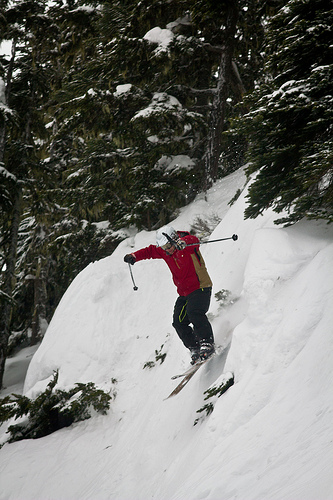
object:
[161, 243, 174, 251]
goggles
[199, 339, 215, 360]
shoes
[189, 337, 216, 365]
boots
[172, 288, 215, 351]
black pants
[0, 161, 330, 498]
snow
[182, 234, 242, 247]
ski pole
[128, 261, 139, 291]
ski pole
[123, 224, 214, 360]
man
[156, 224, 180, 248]
helmet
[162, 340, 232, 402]
skis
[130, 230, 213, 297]
jacket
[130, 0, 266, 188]
trees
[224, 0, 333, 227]
tree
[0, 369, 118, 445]
tree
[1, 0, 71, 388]
tree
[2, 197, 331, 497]
hillside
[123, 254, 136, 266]
black gloves